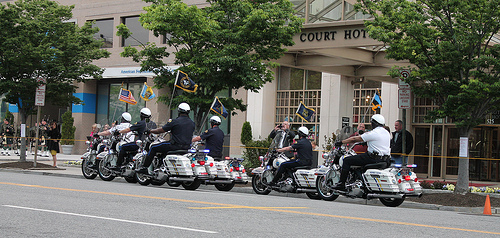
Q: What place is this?
A: It is a road.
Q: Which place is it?
A: It is a road.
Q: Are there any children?
A: No, there are no children.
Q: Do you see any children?
A: No, there are no children.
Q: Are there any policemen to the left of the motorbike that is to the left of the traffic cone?
A: Yes, there is a policeman to the left of the motorbike.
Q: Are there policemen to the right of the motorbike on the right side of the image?
A: No, the policeman is to the left of the motorcycle.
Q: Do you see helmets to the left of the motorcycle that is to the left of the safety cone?
A: No, there is a policeman to the left of the motorbike.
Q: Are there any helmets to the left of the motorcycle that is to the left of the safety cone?
A: No, there is a policeman to the left of the motorbike.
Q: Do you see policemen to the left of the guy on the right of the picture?
A: Yes, there is a policeman to the left of the guy.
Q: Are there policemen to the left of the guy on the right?
A: Yes, there is a policeman to the left of the guy.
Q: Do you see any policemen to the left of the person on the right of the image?
A: Yes, there is a policeman to the left of the guy.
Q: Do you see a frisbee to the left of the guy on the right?
A: No, there is a policeman to the left of the guy.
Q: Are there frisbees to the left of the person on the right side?
A: No, there is a policeman to the left of the guy.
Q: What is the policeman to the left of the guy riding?
A: The policeman is riding a motorcycle.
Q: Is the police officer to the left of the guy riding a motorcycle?
A: Yes, the police officer is riding a motorcycle.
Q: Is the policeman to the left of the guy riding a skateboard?
A: No, the police officer is riding a motorcycle.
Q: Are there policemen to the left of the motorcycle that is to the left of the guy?
A: Yes, there is a policeman to the left of the motorbike.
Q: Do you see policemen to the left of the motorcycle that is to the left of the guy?
A: Yes, there is a policeman to the left of the motorbike.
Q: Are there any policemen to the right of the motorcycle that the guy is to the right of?
A: No, the policeman is to the left of the motorcycle.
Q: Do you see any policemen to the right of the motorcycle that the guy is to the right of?
A: No, the policeman is to the left of the motorcycle.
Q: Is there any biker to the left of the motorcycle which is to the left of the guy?
A: No, there is a policeman to the left of the motorbike.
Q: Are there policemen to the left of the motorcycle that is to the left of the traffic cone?
A: Yes, there is a policeman to the left of the motorbike.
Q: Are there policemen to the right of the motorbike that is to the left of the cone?
A: No, the policeman is to the left of the motorcycle.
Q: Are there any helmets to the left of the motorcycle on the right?
A: No, there is a policeman to the left of the motorcycle.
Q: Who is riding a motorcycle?
A: The police officer is riding a motorcycle.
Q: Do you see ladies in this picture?
A: No, there are no ladies.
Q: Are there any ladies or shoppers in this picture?
A: No, there are no ladies or shoppers.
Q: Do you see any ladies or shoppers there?
A: No, there are no ladies or shoppers.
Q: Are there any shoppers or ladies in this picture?
A: No, there are no ladies or shoppers.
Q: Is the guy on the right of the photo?
A: Yes, the guy is on the right of the image.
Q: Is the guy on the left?
A: No, the guy is on the right of the image.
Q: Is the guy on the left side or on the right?
A: The guy is on the right of the image.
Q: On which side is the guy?
A: The guy is on the right of the image.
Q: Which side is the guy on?
A: The guy is on the right of the image.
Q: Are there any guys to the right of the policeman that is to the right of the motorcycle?
A: Yes, there is a guy to the right of the policeman.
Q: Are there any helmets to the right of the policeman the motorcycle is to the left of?
A: No, there is a guy to the right of the police officer.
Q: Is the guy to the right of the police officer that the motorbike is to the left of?
A: Yes, the guy is to the right of the policeman.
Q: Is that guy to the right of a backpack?
A: No, the guy is to the right of the policeman.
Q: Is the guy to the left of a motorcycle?
A: No, the guy is to the right of a motorcycle.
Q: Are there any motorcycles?
A: Yes, there is a motorcycle.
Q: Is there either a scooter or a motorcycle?
A: Yes, there is a motorcycle.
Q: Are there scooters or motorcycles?
A: Yes, there is a motorcycle.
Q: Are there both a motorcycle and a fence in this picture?
A: No, there is a motorcycle but no fences.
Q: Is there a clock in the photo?
A: No, there are no clocks.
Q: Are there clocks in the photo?
A: No, there are no clocks.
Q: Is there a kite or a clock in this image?
A: No, there are no clocks or kites.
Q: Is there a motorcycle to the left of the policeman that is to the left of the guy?
A: Yes, there is a motorcycle to the left of the police officer.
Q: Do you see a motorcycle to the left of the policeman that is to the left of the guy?
A: Yes, there is a motorcycle to the left of the police officer.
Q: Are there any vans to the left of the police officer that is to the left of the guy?
A: No, there is a motorcycle to the left of the police officer.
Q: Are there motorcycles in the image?
A: Yes, there is a motorcycle.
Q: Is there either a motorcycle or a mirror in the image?
A: Yes, there is a motorcycle.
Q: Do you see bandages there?
A: No, there are no bandages.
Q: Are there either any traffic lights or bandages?
A: No, there are no bandages or traffic lights.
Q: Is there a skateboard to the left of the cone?
A: No, there is a motorcycle to the left of the cone.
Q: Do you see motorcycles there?
A: Yes, there is a motorcycle.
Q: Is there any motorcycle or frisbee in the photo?
A: Yes, there is a motorcycle.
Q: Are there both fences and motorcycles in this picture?
A: No, there is a motorcycle but no fences.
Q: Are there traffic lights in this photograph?
A: No, there are no traffic lights.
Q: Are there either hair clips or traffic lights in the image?
A: No, there are no traffic lights or hair clips.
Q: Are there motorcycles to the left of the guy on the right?
A: Yes, there is a motorcycle to the left of the guy.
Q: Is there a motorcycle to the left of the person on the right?
A: Yes, there is a motorcycle to the left of the guy.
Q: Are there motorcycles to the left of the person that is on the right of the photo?
A: Yes, there is a motorcycle to the left of the guy.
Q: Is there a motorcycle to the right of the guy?
A: No, the motorcycle is to the left of the guy.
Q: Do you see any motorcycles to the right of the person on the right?
A: No, the motorcycle is to the left of the guy.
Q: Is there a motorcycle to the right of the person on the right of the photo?
A: No, the motorcycle is to the left of the guy.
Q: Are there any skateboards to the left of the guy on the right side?
A: No, there is a motorcycle to the left of the guy.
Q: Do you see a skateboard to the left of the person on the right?
A: No, there is a motorcycle to the left of the guy.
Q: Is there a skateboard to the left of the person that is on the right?
A: No, there is a motorcycle to the left of the guy.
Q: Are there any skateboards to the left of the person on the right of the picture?
A: No, there is a motorcycle to the left of the guy.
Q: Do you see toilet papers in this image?
A: No, there are no toilet papers.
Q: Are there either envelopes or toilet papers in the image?
A: No, there are no toilet papers or envelopes.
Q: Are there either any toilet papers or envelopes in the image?
A: No, there are no toilet papers or envelopes.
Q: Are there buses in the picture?
A: No, there are no buses.